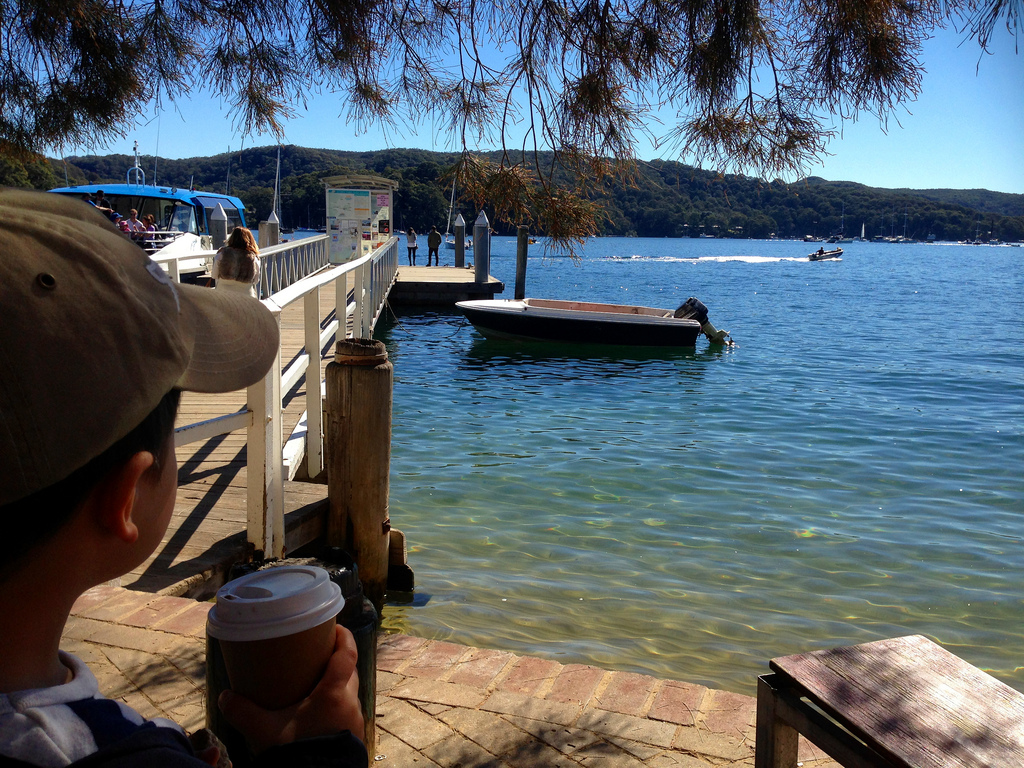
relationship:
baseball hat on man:
[2, 193, 278, 503] [0, 188, 380, 766]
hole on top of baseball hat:
[26, 262, 65, 304] [0, 186, 280, 505]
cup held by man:
[212, 537, 358, 722] [2, 171, 366, 757]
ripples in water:
[451, 351, 892, 604] [418, 231, 1020, 608]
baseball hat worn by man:
[0, 186, 280, 505] [0, 188, 380, 766]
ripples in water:
[451, 351, 894, 622] [418, 231, 1020, 608]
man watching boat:
[13, 186, 417, 759] [472, 290, 714, 355]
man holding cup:
[0, 188, 380, 766] [185, 565, 345, 737]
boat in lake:
[455, 297, 702, 349] [569, 402, 930, 575]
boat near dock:
[455, 297, 702, 349] [286, 186, 528, 444]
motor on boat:
[662, 292, 803, 409] [460, 288, 733, 372]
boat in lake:
[460, 288, 733, 372] [396, 139, 1023, 628]